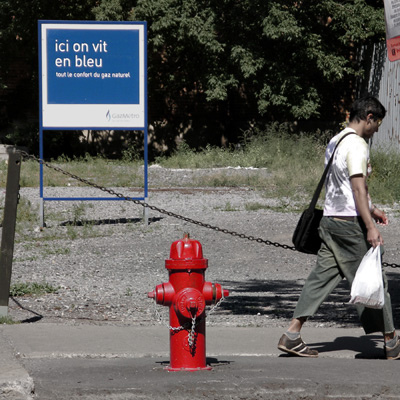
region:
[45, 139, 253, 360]
a red water pipe post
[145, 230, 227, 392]
a red water pipe post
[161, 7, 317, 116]
tree branches and leaves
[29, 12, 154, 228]
blue and white sign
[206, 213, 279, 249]
single chain fence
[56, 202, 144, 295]
stone gravel driveway with weeds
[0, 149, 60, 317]
metal fence post with chain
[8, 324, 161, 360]
concrete sidewalk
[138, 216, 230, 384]
red fire hydrant on street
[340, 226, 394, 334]
white plastic grocery bag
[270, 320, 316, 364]
brown and white sneaker with white stripes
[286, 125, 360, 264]
black laptop carrying bag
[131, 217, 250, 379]
a red fire hydrant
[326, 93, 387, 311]
a man holding a white bag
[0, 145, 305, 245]
a chain attached to a pole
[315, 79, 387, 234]
a man wearing a white shirt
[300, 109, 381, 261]
a man with a black shoulder bag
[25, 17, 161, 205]
a blue and white sign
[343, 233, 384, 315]
a white plastic bag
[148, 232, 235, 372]
a red fire hydrant with chains attaced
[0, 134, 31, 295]
a metal pole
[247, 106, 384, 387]
a man walking on a sidewalk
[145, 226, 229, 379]
The fire hydrant is red.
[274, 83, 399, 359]
The man is walking.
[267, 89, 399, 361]
The man is carying a bag.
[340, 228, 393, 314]
The bag is white.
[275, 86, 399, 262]
The man is carrying a satchel.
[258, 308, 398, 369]
The shoes are brown.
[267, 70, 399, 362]
The man is wearing shoes.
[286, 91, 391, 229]
The man is wearing a shirt.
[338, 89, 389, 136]
The man has dark hair.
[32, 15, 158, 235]
The sign is not in English.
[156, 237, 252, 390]
A red pipe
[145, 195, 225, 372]
A red pipe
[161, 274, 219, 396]
A red pipe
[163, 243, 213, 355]
A red pipe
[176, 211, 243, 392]
A red pipe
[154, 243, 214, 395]
A red pipe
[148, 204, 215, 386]
A red pipe